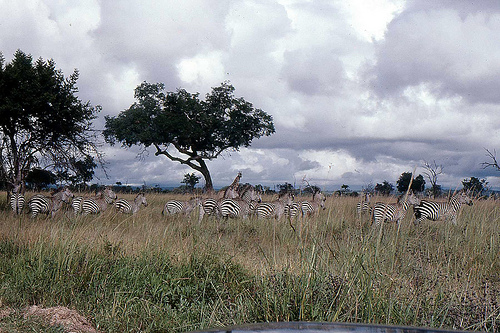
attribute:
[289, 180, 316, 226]
zebra — black, white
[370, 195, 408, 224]
zebra — black, white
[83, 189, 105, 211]
zebra — black, white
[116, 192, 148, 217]
zebra — black, white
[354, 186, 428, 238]
zebra — White, black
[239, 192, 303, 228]
zebra — black, white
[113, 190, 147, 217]
white zebra — black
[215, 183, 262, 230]
zebra — black, White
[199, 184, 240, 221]
zebra — black, White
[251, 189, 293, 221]
zebra — black, White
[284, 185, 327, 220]
zebra — black, White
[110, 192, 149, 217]
zebra — black, White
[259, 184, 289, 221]
zebra — white, black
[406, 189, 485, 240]
zebra — black, white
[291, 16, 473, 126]
sky — cloudy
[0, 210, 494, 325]
grass — brown 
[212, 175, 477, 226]
zebras — looking